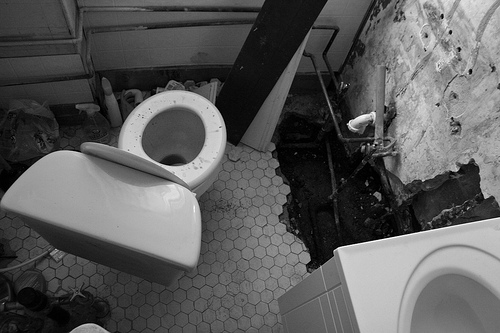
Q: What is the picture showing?
A: It is showing a bathroom.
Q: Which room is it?
A: It is a bathroom.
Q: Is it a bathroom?
A: Yes, it is a bathroom.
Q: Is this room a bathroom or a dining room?
A: It is a bathroom.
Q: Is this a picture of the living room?
A: No, the picture is showing the bathroom.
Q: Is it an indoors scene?
A: Yes, it is indoors.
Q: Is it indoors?
A: Yes, it is indoors.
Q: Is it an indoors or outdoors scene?
A: It is indoors.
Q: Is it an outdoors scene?
A: No, it is indoors.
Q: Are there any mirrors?
A: No, there are no mirrors.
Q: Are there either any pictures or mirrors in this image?
A: No, there are no mirrors or pictures.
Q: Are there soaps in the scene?
A: No, there are no soaps.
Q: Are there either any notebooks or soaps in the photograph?
A: No, there are no soaps or notebooks.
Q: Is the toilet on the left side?
A: Yes, the toilet is on the left of the image.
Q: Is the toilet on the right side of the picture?
A: No, the toilet is on the left of the image.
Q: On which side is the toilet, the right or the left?
A: The toilet is on the left of the image.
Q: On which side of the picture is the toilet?
A: The toilet is on the left of the image.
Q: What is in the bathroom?
A: The toilet is in the bathroom.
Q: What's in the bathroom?
A: The toilet is in the bathroom.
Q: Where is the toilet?
A: The toilet is in the bathroom.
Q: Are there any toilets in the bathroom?
A: Yes, there is a toilet in the bathroom.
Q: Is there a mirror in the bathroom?
A: No, there is a toilet in the bathroom.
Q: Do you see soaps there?
A: No, there are no soaps.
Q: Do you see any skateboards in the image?
A: No, there are no skateboards.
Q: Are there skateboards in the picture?
A: No, there are no skateboards.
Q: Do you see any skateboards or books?
A: No, there are no skateboards or books.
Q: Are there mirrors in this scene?
A: No, there are no mirrors.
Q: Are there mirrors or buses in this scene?
A: No, there are no mirrors or buses.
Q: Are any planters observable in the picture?
A: No, there are no planters.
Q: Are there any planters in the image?
A: No, there are no planters.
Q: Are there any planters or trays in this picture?
A: No, there are no planters or trays.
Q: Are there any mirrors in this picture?
A: No, there are no mirrors.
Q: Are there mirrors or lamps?
A: No, there are no mirrors or lamps.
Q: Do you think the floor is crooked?
A: Yes, the floor is crooked.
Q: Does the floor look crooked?
A: Yes, the floor is crooked.